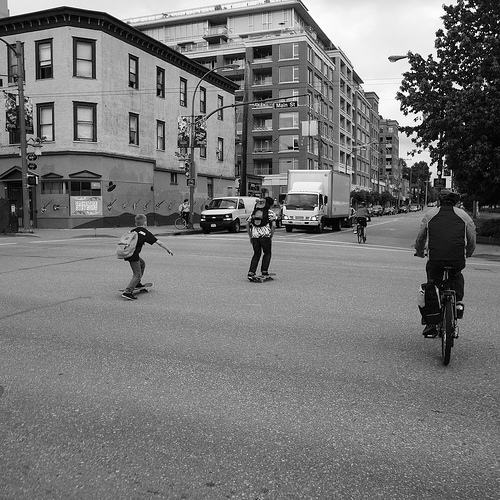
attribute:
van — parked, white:
[201, 195, 262, 232]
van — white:
[195, 173, 263, 241]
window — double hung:
[73, 100, 95, 141]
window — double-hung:
[125, 110, 145, 155]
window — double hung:
[72, 37, 95, 80]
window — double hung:
[73, 102, 99, 138]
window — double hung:
[37, 42, 53, 77]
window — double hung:
[36, 105, 52, 142]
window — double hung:
[127, 52, 137, 92]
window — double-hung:
[127, 55, 137, 89]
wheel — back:
[436, 299, 456, 368]